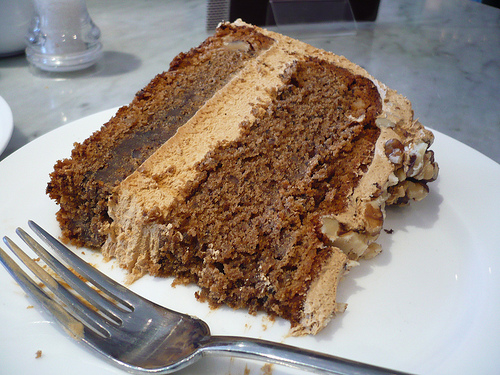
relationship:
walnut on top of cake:
[316, 211, 372, 263] [53, 33, 448, 310]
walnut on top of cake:
[376, 132, 406, 171] [53, 33, 448, 310]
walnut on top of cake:
[404, 135, 441, 184] [53, 33, 448, 310]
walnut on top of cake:
[387, 174, 432, 206] [53, 33, 448, 310]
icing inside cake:
[260, 50, 295, 80] [46, 17, 439, 336]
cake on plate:
[46, 17, 439, 336] [0, 103, 497, 373]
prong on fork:
[1, 221, 134, 341] [0, 218, 394, 373]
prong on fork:
[1, 234, 120, 333] [0, 218, 394, 373]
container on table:
[22, 1, 107, 74] [0, 0, 500, 161]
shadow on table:
[55, 41, 142, 77] [0, 0, 500, 161]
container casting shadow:
[22, 1, 107, 74] [55, 41, 142, 77]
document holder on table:
[267, 6, 387, 42] [7, 84, 494, 373]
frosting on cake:
[296, 73, 435, 335] [46, 17, 439, 336]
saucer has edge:
[3, 100, 499, 373] [2, 95, 19, 156]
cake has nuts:
[46, 17, 439, 336] [330, 116, 465, 236]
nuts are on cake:
[330, 116, 465, 236] [46, 17, 439, 336]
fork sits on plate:
[0, 218, 394, 373] [0, 103, 497, 373]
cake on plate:
[46, 17, 439, 336] [2, 144, 487, 374]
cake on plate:
[112, 81, 467, 266] [0, 103, 497, 373]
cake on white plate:
[46, 17, 439, 336] [1, 101, 498, 373]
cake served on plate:
[46, 17, 439, 336] [0, 103, 497, 373]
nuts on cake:
[382, 138, 401, 163] [46, 17, 439, 336]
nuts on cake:
[316, 214, 347, 244] [46, 17, 439, 336]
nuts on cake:
[359, 204, 386, 231] [46, 17, 439, 336]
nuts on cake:
[423, 149, 437, 181] [46, 17, 439, 336]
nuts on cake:
[399, 177, 429, 199] [46, 17, 439, 336]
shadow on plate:
[404, 193, 459, 242] [1, 57, 471, 300]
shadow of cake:
[404, 193, 459, 242] [46, 17, 439, 336]